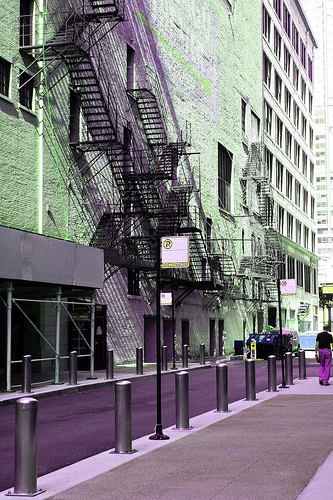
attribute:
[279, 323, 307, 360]
van — parked , distance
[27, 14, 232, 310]
ladders — black 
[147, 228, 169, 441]
pole — large , silver , metal 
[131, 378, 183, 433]
street — black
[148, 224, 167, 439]
post — black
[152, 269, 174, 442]
pole — metal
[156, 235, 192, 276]
sign — red, white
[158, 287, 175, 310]
sign — white, red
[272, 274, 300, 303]
sign — white, red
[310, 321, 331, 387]
person — walking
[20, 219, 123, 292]
awning — grey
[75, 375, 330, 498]
sidewalk — grey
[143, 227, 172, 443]
pole — metal 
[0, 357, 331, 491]
road — dark, grey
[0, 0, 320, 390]
sidewalk — white 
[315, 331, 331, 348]
shirt — black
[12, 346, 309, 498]
poles — grey 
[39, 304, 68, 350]
post — grey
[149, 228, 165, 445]
pole — black